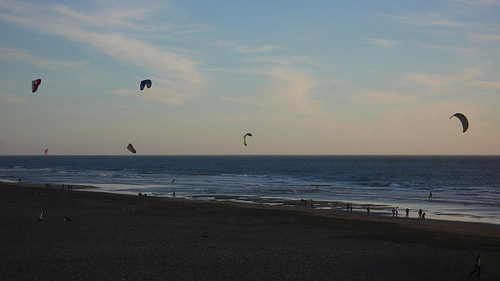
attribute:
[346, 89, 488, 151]
clouds — White 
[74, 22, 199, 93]
clouds — White 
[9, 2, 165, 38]
clouds — White 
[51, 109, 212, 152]
clouds — White 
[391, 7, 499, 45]
clouds — White 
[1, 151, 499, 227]
ocean — Large , dark blue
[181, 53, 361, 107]
clouds — White 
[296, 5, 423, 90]
sky — blue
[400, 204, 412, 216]
person — Walking 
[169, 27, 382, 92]
sky — Blue 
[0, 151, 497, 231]
water — Blue 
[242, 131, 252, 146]
kite — Silver , Curved 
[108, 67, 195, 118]
kite — Large 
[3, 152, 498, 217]
water — Blue 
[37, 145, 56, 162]
kite — red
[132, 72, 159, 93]
kite — Large 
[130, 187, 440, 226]
people — Walking 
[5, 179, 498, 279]
beach — brown, sandy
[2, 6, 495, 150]
sky — Blue 